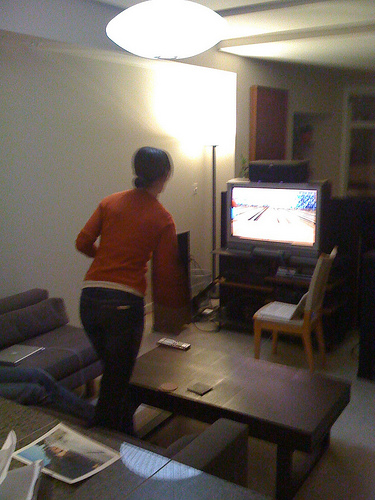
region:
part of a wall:
[7, 126, 48, 184]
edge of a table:
[269, 417, 291, 448]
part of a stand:
[277, 455, 295, 480]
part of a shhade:
[336, 452, 359, 488]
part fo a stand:
[279, 451, 289, 474]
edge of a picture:
[75, 460, 105, 486]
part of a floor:
[328, 450, 353, 484]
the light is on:
[113, 14, 224, 59]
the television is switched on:
[221, 186, 320, 254]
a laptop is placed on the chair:
[259, 293, 305, 331]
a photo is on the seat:
[18, 434, 117, 488]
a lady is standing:
[77, 145, 179, 403]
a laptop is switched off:
[2, 343, 55, 362]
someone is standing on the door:
[289, 128, 324, 168]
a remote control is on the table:
[157, 333, 189, 351]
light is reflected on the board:
[152, 75, 230, 141]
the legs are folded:
[5, 364, 73, 410]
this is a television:
[225, 176, 321, 238]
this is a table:
[218, 358, 321, 463]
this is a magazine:
[31, 437, 96, 488]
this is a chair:
[255, 268, 326, 337]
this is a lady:
[113, 144, 160, 407]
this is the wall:
[17, 150, 70, 237]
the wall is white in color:
[22, 108, 93, 205]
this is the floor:
[344, 425, 352, 443]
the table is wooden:
[242, 364, 291, 414]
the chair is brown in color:
[300, 325, 314, 349]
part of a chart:
[173, 102, 195, 119]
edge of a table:
[280, 430, 301, 448]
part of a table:
[272, 424, 296, 448]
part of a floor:
[322, 468, 339, 486]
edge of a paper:
[80, 473, 97, 489]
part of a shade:
[334, 444, 358, 475]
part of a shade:
[153, 476, 169, 491]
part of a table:
[279, 419, 303, 443]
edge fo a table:
[277, 425, 301, 444]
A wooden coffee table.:
[94, 338, 346, 492]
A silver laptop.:
[2, 340, 44, 366]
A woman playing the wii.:
[68, 147, 188, 429]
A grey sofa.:
[0, 293, 116, 403]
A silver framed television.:
[223, 177, 326, 268]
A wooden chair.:
[242, 249, 334, 371]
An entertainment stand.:
[212, 242, 345, 349]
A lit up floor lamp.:
[198, 123, 229, 305]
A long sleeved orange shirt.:
[77, 186, 185, 301]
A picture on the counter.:
[14, 424, 121, 487]